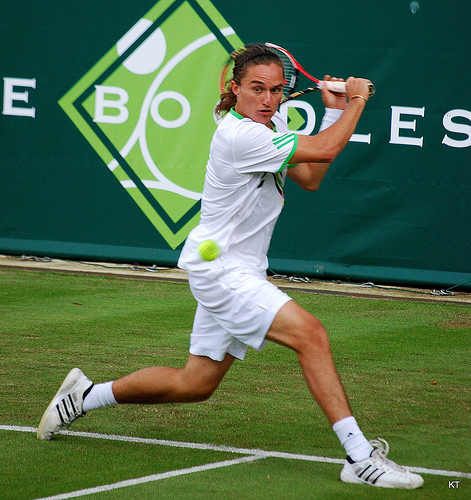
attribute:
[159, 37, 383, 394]
player — swinging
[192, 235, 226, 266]
ball — green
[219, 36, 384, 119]
racket — white, red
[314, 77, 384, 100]
handle — white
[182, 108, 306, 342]
clothes — white, green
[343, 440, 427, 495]
shoe — white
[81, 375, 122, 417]
socks — white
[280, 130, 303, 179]
border — green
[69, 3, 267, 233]
diamond — green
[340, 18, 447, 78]
wall — green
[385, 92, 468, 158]
letters — white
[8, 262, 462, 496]
court — grassy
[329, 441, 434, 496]
shoes — black, white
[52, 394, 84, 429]
stripes — green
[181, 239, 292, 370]
shorts — white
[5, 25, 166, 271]
banner — green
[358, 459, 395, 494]
lines — black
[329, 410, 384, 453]
sock — white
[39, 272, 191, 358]
field — green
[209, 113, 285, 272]
shirt — white